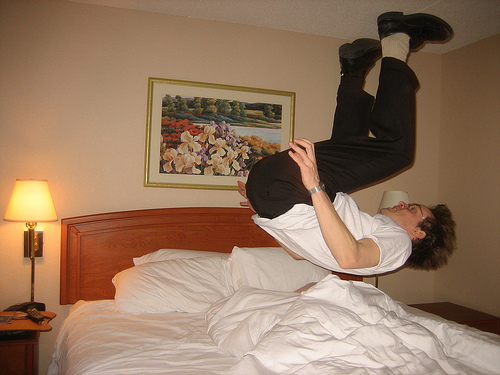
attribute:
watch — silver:
[307, 183, 328, 192]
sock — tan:
[378, 35, 416, 61]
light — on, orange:
[9, 171, 55, 325]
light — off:
[375, 183, 409, 289]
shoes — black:
[310, 10, 459, 71]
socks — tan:
[378, 36, 418, 66]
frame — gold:
[123, 62, 305, 204]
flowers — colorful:
[177, 138, 272, 162]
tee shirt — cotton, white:
[247, 190, 411, 275]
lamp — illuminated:
[7, 145, 84, 333]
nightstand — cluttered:
[4, 297, 56, 368]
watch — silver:
[282, 172, 340, 204]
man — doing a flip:
[238, 5, 469, 279]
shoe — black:
[374, 7, 456, 54]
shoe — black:
[335, 36, 382, 78]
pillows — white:
[114, 244, 331, 306]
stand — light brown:
[4, 271, 61, 371]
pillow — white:
[108, 258, 235, 318]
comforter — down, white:
[53, 270, 498, 372]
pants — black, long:
[240, 57, 422, 214]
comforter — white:
[205, 274, 457, 374]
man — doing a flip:
[208, 38, 440, 285]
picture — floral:
[141, 81, 312, 195]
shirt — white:
[225, 199, 417, 284]